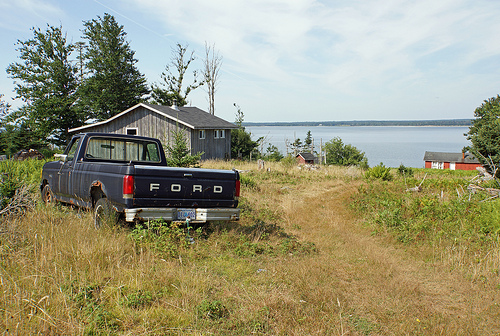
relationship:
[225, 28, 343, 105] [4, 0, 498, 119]
clouds in sky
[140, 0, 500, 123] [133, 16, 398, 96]
clouds in blue sky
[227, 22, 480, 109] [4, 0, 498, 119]
clouds in sky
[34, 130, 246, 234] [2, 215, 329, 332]
truck on grass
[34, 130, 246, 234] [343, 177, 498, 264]
truck on grass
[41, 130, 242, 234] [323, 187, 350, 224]
truck in grass